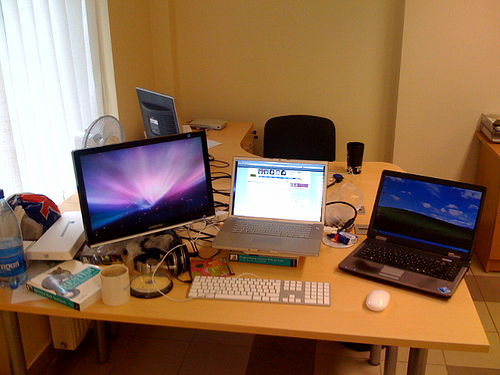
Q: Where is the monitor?
A: To the left of the laptop.